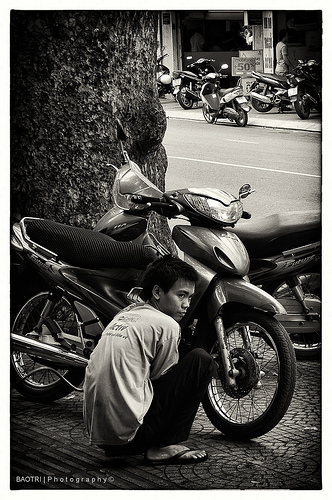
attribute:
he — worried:
[84, 250, 227, 466]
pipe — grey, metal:
[15, 322, 90, 375]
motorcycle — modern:
[14, 177, 297, 450]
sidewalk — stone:
[46, 323, 323, 488]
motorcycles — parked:
[206, 71, 285, 143]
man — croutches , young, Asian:
[85, 249, 222, 467]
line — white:
[179, 154, 285, 180]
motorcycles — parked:
[10, 111, 323, 442]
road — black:
[181, 112, 306, 189]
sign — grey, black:
[229, 55, 265, 76]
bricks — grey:
[239, 448, 314, 490]